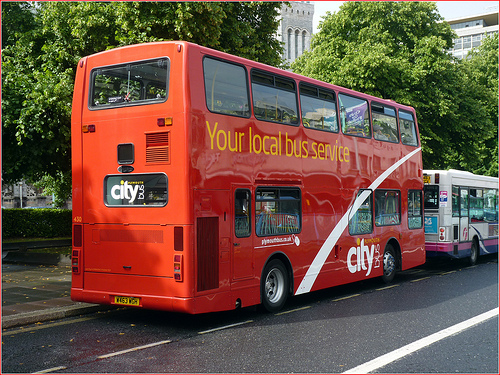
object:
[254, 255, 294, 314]
tire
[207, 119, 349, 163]
writing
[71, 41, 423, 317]
bus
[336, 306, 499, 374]
line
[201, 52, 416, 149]
window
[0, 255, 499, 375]
road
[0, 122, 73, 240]
bush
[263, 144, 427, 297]
stripe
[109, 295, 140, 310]
plate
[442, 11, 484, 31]
hedgerow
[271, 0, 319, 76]
building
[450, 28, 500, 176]
trees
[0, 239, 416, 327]
sidewalk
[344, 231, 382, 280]
brand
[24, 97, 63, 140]
leaves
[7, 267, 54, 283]
drain